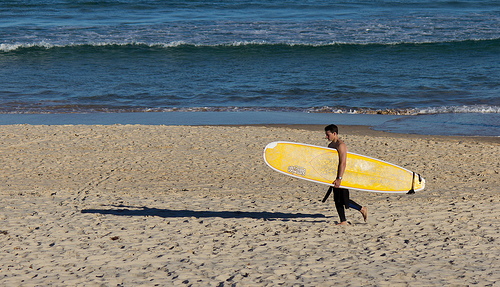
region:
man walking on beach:
[241, 119, 416, 221]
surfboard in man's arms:
[265, 141, 432, 199]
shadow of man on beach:
[85, 201, 350, 222]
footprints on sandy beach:
[380, 201, 490, 256]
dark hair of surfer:
[325, 115, 344, 142]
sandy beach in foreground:
[14, 119, 428, 281]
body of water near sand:
[19, 2, 496, 143]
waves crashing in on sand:
[407, 97, 499, 119]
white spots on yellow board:
[265, 138, 276, 148]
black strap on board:
[402, 162, 420, 197]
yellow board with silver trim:
[265, 142, 427, 194]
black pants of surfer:
[332, 186, 361, 220]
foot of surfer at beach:
[357, 208, 371, 219]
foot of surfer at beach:
[333, 219, 349, 224]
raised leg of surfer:
[346, 198, 367, 223]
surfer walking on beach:
[267, 116, 427, 220]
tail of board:
[412, 170, 427, 193]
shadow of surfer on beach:
[81, 210, 322, 218]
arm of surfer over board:
[331, 138, 349, 189]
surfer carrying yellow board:
[259, 124, 424, 226]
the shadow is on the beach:
[68, 180, 253, 252]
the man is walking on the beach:
[232, 125, 450, 250]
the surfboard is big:
[253, 139, 436, 211]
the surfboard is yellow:
[253, 137, 434, 210]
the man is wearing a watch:
[323, 167, 348, 185]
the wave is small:
[66, 39, 375, 64]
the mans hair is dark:
[323, 119, 341, 131]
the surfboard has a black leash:
[403, 174, 423, 197]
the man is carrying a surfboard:
[252, 109, 447, 240]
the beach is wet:
[125, 113, 247, 126]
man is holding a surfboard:
[265, 114, 427, 217]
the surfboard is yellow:
[258, 140, 428, 201]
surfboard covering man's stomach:
[260, 144, 427, 195]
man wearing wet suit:
[322, 186, 363, 224]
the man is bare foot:
[333, 208, 375, 228]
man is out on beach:
[1, 3, 498, 284]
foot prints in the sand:
[1, 123, 498, 281]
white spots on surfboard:
[262, 142, 427, 194]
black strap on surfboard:
[404, 165, 426, 198]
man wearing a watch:
[335, 174, 347, 184]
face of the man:
[322, 114, 347, 136]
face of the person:
[312, 122, 352, 138]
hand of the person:
[321, 158, 356, 193]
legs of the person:
[325, 181, 353, 206]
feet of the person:
[362, 198, 382, 231]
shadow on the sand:
[123, 192, 201, 232]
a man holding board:
[302, 117, 391, 250]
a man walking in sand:
[283, 101, 400, 256]